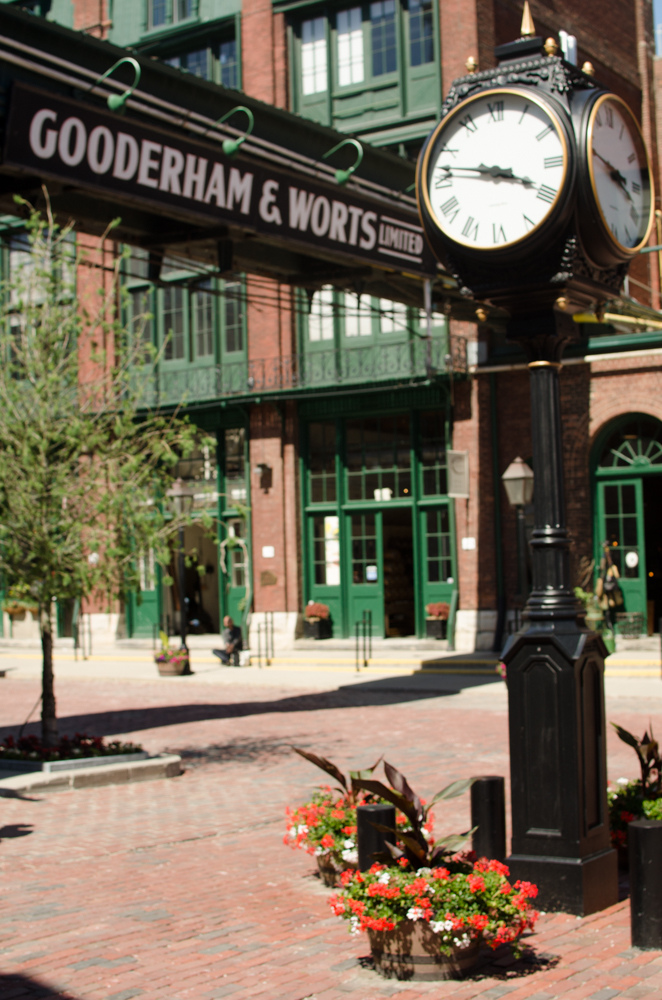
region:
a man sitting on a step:
[215, 613, 245, 665]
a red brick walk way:
[131, 786, 274, 937]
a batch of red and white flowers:
[344, 859, 530, 949]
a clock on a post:
[415, 68, 625, 876]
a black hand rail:
[349, 605, 377, 676]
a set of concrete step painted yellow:
[288, 643, 383, 680]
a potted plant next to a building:
[302, 598, 329, 644]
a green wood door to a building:
[350, 506, 393, 639]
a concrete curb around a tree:
[62, 757, 175, 798]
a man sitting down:
[207, 612, 246, 670]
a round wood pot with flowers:
[358, 876, 537, 978]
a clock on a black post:
[408, 16, 605, 910]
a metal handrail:
[346, 599, 379, 684]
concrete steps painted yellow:
[270, 655, 352, 673]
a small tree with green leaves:
[0, 345, 166, 762]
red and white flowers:
[346, 849, 531, 935]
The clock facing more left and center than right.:
[416, 86, 569, 246]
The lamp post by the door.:
[503, 448, 540, 644]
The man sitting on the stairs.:
[209, 607, 244, 665]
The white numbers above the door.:
[368, 486, 394, 499]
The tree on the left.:
[0, 242, 225, 767]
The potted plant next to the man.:
[153, 643, 183, 678]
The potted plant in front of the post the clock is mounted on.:
[344, 859, 540, 981]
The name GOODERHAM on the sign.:
[32, 104, 258, 217]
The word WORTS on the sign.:
[281, 183, 383, 249]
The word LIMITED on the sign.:
[378, 206, 434, 264]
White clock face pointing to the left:
[432, 57, 575, 293]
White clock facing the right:
[581, 72, 641, 280]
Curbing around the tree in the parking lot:
[35, 576, 154, 824]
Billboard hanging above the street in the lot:
[70, 55, 430, 317]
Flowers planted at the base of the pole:
[305, 718, 574, 958]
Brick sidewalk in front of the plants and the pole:
[41, 821, 439, 968]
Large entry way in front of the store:
[299, 481, 459, 669]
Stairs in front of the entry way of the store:
[255, 579, 431, 700]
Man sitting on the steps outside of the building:
[203, 591, 271, 695]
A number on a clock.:
[489, 217, 513, 251]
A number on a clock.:
[519, 211, 533, 239]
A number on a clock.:
[533, 184, 561, 203]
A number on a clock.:
[542, 152, 573, 167]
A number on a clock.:
[536, 119, 558, 138]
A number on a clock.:
[514, 94, 532, 128]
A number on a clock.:
[483, 91, 505, 125]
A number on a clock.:
[454, 112, 479, 136]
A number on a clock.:
[441, 188, 459, 217]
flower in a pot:
[406, 872, 421, 896]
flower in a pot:
[437, 902, 454, 928]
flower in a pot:
[479, 903, 504, 939]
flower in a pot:
[454, 899, 491, 927]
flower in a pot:
[513, 922, 528, 937]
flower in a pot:
[497, 857, 531, 905]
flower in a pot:
[477, 843, 496, 879]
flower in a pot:
[343, 848, 385, 893]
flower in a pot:
[326, 886, 352, 920]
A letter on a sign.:
[23, 103, 60, 165]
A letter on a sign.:
[53, 112, 85, 173]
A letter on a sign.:
[89, 125, 116, 174]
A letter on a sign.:
[112, 124, 138, 184]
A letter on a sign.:
[136, 134, 161, 192]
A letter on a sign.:
[155, 140, 181, 199]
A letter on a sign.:
[183, 150, 210, 200]